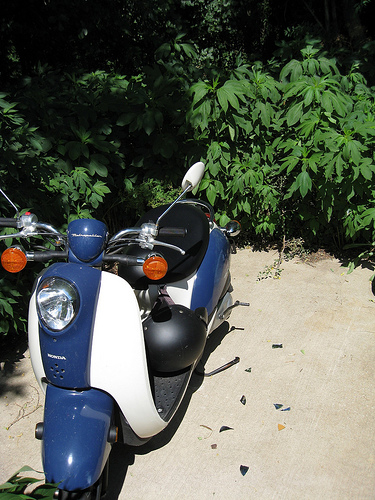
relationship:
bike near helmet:
[19, 172, 230, 456] [142, 305, 213, 367]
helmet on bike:
[142, 305, 213, 367] [19, 172, 230, 456]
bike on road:
[19, 172, 230, 456] [258, 306, 340, 436]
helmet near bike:
[142, 305, 213, 367] [19, 172, 230, 456]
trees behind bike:
[265, 45, 356, 146] [19, 172, 230, 456]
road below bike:
[258, 306, 340, 436] [19, 172, 230, 456]